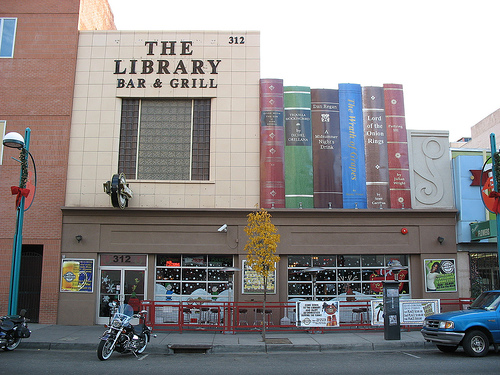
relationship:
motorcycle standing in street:
[98, 297, 162, 364] [0, 347, 498, 373]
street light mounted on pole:
[2, 132, 22, 148] [1, 126, 41, 315]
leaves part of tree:
[243, 207, 281, 342] [230, 203, 295, 350]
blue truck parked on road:
[420, 290, 499, 358] [7, 349, 498, 366]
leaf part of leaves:
[265, 210, 272, 222] [243, 207, 281, 342]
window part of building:
[118, 97, 212, 180] [56, 29, 461, 330]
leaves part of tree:
[243, 207, 281, 278] [243, 206, 279, 348]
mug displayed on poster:
[59, 260, 88, 290] [60, 253, 115, 311]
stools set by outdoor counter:
[167, 296, 384, 334] [116, 290, 488, 339]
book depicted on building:
[382, 83, 413, 208] [56, 16, 459, 352]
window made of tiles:
[118, 97, 212, 182] [134, 99, 192, 177]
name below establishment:
[112, 40, 220, 89] [55, 32, 457, 332]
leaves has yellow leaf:
[243, 207, 281, 342] [271, 252, 281, 262]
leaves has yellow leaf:
[243, 207, 281, 342] [266, 240, 279, 254]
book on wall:
[256, 75, 286, 210] [0, 0, 465, 332]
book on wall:
[347, 75, 398, 210] [0, 0, 465, 332]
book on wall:
[382, 83, 413, 208] [148, 258, 235, 338]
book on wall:
[384, 84, 416, 210] [72, 25, 262, 238]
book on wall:
[361, 84, 396, 209] [66, 214, 460, 320]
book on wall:
[338, 82, 367, 209] [0, 3, 75, 338]